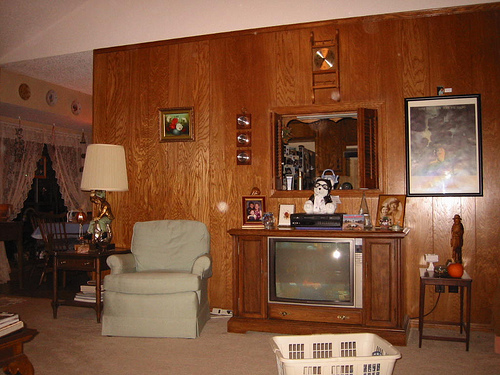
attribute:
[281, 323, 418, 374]
basket — white, laundry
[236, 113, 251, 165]
plaques — black, gold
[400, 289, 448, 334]
cord — black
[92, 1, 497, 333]
paneling — wooden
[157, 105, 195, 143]
painting — small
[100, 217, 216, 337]
chair — reclining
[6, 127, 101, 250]
curtains — lace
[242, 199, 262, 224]
portrait — family, wooden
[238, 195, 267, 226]
frame — brown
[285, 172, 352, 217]
bear — white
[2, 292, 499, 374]
carpet — tan, beige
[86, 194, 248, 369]
armchair — gray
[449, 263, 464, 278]
pumpkin — orange, ceramic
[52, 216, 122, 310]
table — small, wood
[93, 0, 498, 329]
panelled wall — wood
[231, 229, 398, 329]
cabinet television — wood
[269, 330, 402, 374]
basket — tan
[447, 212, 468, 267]
statue — wood, small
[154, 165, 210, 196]
wall — brown, wood, panelled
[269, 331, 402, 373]
laundry basket — white, plastic